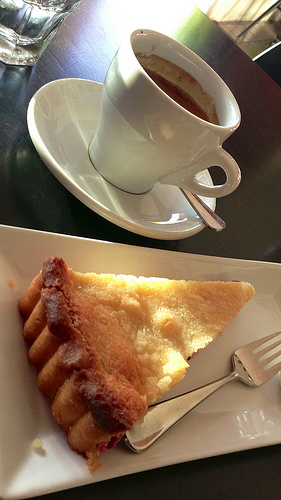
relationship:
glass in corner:
[2, 2, 79, 73] [2, 2, 131, 136]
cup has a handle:
[88, 27, 242, 198] [159, 146, 240, 200]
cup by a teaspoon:
[88, 27, 242, 198] [178, 188, 226, 232]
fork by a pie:
[123, 331, 279, 454] [18, 256, 255, 472]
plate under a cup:
[27, 76, 217, 240] [88, 27, 242, 198]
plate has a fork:
[3, 223, 277, 499] [123, 331, 279, 454]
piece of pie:
[167, 272, 258, 349] [18, 256, 255, 472]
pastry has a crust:
[18, 256, 255, 472] [15, 257, 131, 472]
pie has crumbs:
[18, 256, 255, 472] [26, 421, 66, 470]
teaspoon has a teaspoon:
[178, 188, 226, 232] [178, 188, 226, 232]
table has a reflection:
[9, 6, 276, 266] [6, 124, 77, 232]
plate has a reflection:
[27, 76, 215, 242] [55, 110, 81, 150]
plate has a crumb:
[27, 76, 215, 242] [30, 438, 43, 454]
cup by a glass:
[86, 27, 243, 199] [2, 2, 79, 73]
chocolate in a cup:
[137, 51, 218, 126] [86, 27, 243, 199]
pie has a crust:
[18, 256, 255, 472] [15, 257, 131, 472]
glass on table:
[2, 2, 79, 73] [9, 6, 276, 266]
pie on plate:
[18, 256, 255, 472] [0, 223, 281, 499]